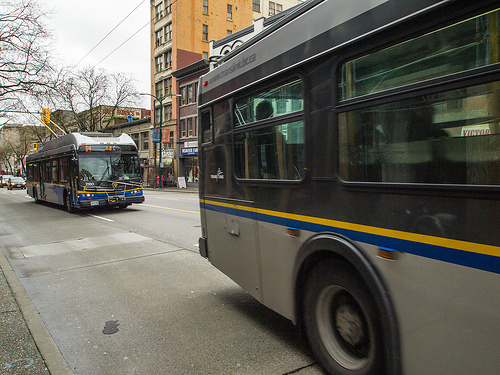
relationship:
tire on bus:
[285, 236, 396, 370] [197, 32, 486, 307]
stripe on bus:
[198, 193, 497, 296] [191, 14, 497, 336]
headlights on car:
[78, 189, 103, 212] [3, 175, 24, 190]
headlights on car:
[121, 182, 148, 207] [3, 175, 24, 190]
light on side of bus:
[370, 243, 404, 266] [5, 125, 146, 218]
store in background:
[150, 147, 177, 187] [2, 0, 298, 219]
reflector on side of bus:
[285, 228, 300, 238] [195, 3, 499, 373]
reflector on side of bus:
[375, 246, 399, 260] [195, 3, 499, 373]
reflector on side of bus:
[285, 228, 300, 238] [22, 126, 147, 218]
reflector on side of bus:
[285, 228, 300, 238] [221, 29, 498, 253]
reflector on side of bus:
[77, 187, 104, 198] [17, 102, 179, 221]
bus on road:
[202, 77, 402, 280] [2, 177, 342, 362]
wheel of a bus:
[61, 189, 76, 212] [22, 131, 151, 211]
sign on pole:
[162, 127, 170, 141] [157, 97, 163, 182]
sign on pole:
[152, 130, 161, 143] [157, 97, 163, 182]